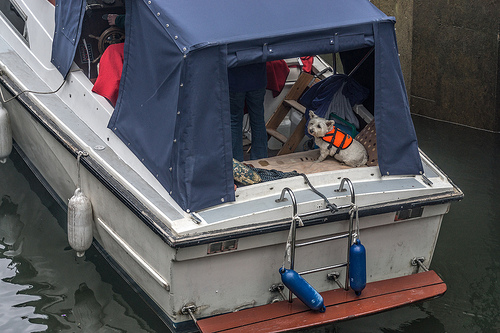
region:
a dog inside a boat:
[300, 99, 444, 245]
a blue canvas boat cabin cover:
[97, 6, 429, 196]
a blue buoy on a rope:
[342, 224, 381, 306]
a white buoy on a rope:
[55, 165, 98, 268]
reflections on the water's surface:
[3, 223, 61, 331]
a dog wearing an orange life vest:
[302, 108, 377, 169]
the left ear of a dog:
[329, 118, 336, 130]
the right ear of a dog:
[305, 108, 318, 120]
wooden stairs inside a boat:
[260, 67, 322, 156]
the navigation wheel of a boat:
[88, 15, 133, 68]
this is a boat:
[68, 39, 463, 299]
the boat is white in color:
[106, 214, 145, 264]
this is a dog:
[298, 114, 365, 156]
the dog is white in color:
[345, 146, 365, 159]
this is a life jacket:
[333, 127, 353, 139]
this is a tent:
[148, 45, 196, 125]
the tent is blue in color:
[165, 31, 197, 95]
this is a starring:
[92, 27, 122, 40]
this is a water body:
[458, 214, 494, 306]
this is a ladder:
[275, 95, 296, 142]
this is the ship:
[99, 9, 389, 277]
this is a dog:
[303, 111, 365, 158]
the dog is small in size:
[302, 110, 363, 162]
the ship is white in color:
[177, 252, 249, 300]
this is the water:
[38, 272, 108, 329]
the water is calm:
[0, 258, 97, 328]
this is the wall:
[421, 6, 483, 86]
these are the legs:
[235, 96, 263, 150]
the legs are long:
[233, 91, 265, 151]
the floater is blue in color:
[353, 239, 366, 292]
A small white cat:
[314, 118, 364, 153]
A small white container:
[61, 179, 101, 263]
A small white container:
[2, 93, 19, 169]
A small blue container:
[272, 265, 325, 311]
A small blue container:
[335, 228, 374, 298]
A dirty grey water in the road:
[20, 266, 75, 305]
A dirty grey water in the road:
[7, 179, 60, 249]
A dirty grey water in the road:
[473, 241, 495, 331]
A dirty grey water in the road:
[461, 140, 493, 258]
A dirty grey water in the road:
[414, 306, 447, 323]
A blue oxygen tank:
[278, 267, 331, 314]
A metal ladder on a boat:
[271, 176, 356, 288]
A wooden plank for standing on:
[182, 265, 451, 332]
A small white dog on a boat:
[305, 114, 370, 165]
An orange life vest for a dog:
[323, 122, 354, 155]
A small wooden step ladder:
[256, 64, 326, 154]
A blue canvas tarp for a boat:
[55, 2, 430, 210]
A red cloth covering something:
[90, 39, 127, 104]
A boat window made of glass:
[0, 0, 35, 43]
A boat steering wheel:
[85, 12, 132, 70]